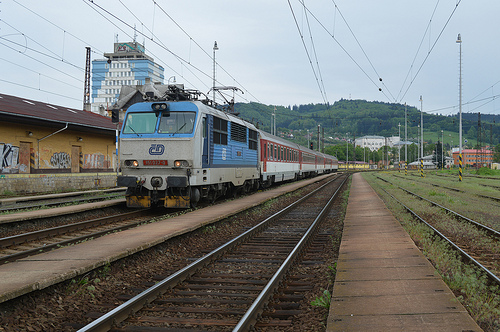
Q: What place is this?
A: It is a railroad.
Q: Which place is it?
A: It is a railroad.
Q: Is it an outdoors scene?
A: Yes, it is outdoors.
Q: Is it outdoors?
A: Yes, it is outdoors.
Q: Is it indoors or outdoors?
A: It is outdoors.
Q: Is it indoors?
A: No, it is outdoors.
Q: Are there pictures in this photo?
A: No, there are no pictures.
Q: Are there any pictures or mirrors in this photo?
A: No, there are no pictures or mirrors.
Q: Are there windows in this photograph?
A: Yes, there are windows.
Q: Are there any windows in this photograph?
A: Yes, there are windows.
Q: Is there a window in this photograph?
A: Yes, there are windows.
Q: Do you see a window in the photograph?
A: Yes, there are windows.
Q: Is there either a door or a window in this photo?
A: Yes, there are windows.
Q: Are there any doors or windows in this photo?
A: Yes, there are windows.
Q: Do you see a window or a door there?
A: Yes, there are windows.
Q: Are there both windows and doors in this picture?
A: Yes, there are both windows and a door.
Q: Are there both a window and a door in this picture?
A: Yes, there are both a window and a door.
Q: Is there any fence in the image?
A: No, there are no fences.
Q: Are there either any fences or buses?
A: No, there are no fences or buses.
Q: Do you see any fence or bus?
A: No, there are no fences or buses.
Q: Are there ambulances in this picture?
A: No, there are no ambulances.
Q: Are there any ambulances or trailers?
A: No, there are no ambulances or trailers.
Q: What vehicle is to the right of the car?
A: The vehicle is a train car.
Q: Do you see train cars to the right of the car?
A: Yes, there is a train car to the right of the car.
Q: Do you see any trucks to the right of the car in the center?
A: No, there is a train car to the right of the car.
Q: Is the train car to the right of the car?
A: Yes, the train car is to the right of the car.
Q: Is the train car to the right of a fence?
A: No, the train car is to the right of the car.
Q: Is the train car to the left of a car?
A: No, the train car is to the right of a car.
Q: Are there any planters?
A: No, there are no planters.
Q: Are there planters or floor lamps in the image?
A: No, there are no planters or floor lamps.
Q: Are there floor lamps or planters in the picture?
A: No, there are no planters or floor lamps.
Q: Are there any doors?
A: Yes, there is a door.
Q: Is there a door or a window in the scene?
A: Yes, there is a door.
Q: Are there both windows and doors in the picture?
A: Yes, there are both a door and a window.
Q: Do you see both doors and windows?
A: Yes, there are both a door and a window.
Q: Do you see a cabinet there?
A: No, there are no cabinets.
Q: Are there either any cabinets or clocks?
A: No, there are no cabinets or clocks.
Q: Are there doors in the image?
A: Yes, there is a door.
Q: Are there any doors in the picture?
A: Yes, there is a door.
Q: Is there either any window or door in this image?
A: Yes, there is a door.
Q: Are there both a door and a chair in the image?
A: No, there is a door but no chairs.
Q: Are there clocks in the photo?
A: No, there are no clocks.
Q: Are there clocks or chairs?
A: No, there are no clocks or chairs.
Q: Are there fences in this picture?
A: No, there are no fences.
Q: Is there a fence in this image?
A: No, there are no fences.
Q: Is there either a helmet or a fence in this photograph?
A: No, there are no fences or helmets.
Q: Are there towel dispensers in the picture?
A: No, there are no towel dispensers.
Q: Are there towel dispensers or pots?
A: No, there are no towel dispensers or pots.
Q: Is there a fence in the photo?
A: No, there are no fences.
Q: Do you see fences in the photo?
A: No, there are no fences.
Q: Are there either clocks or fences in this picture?
A: No, there are no fences or clocks.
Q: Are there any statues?
A: No, there are no statues.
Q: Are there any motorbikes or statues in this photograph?
A: No, there are no statues or motorbikes.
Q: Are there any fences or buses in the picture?
A: No, there are no fences or buses.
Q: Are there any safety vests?
A: No, there are no safety vests.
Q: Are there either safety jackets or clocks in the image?
A: No, there are no safety jackets or clocks.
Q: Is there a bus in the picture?
A: No, there are no buses.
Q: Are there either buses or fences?
A: No, there are no buses or fences.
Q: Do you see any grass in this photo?
A: Yes, there is grass.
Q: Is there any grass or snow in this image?
A: Yes, there is grass.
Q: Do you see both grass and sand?
A: No, there is grass but no sand.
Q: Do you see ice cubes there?
A: No, there are no ice cubes.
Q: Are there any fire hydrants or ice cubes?
A: No, there are no ice cubes or fire hydrants.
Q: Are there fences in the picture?
A: No, there are no fences.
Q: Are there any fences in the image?
A: No, there are no fences.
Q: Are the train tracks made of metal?
A: Yes, the train tracks are made of metal.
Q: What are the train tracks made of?
A: The tracks are made of metal.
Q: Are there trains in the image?
A: Yes, there is a train.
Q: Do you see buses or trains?
A: Yes, there is a train.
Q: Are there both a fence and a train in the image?
A: No, there is a train but no fences.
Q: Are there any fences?
A: No, there are no fences.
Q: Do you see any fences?
A: No, there are no fences.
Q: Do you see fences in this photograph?
A: No, there are no fences.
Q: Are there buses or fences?
A: No, there are no fences or buses.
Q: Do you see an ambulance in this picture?
A: No, there are no ambulances.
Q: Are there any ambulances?
A: No, there are no ambulances.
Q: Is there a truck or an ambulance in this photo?
A: No, there are no ambulances or trucks.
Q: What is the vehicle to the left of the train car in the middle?
A: The vehicle is a car.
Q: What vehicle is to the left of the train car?
A: The vehicle is a car.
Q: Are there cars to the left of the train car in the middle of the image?
A: Yes, there is a car to the left of the train car.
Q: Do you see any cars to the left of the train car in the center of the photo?
A: Yes, there is a car to the left of the train car.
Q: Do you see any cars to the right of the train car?
A: No, the car is to the left of the train car.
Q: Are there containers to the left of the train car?
A: No, there is a car to the left of the train car.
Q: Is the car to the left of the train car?
A: Yes, the car is to the left of the train car.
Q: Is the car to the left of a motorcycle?
A: No, the car is to the left of the train car.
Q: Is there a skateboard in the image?
A: No, there are no skateboards.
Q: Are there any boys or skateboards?
A: No, there are no skateboards or boys.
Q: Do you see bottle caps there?
A: No, there are no bottle caps.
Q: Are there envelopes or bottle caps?
A: No, there are no bottle caps or envelopes.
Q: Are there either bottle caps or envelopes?
A: No, there are no bottle caps or envelopes.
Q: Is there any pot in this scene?
A: No, there are no pots.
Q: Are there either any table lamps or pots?
A: No, there are no pots or table lamps.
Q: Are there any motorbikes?
A: No, there are no motorbikes.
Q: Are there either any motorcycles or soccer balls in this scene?
A: No, there are no motorcycles or soccer balls.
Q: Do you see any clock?
A: No, there are no clocks.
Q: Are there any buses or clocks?
A: No, there are no clocks or buses.